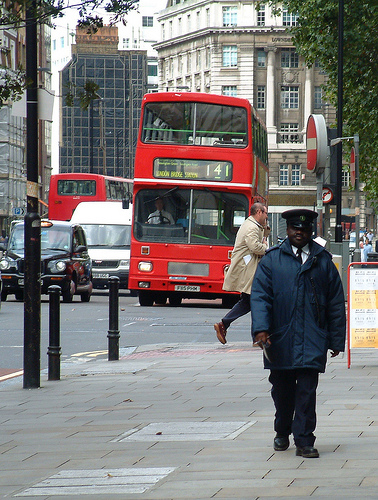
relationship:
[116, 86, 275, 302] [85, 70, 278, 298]
windshield on bus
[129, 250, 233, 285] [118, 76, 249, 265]
headlight on bus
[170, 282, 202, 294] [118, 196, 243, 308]
plate on bus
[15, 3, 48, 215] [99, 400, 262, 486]
pole on sidewalk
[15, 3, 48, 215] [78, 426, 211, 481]
pole on sidewalk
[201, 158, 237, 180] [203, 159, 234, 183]
number on bus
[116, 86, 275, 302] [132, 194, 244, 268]
windshield on bottom deck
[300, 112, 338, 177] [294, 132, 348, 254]
sign on pole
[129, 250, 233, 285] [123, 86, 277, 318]
headlight on bus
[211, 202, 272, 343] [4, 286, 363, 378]
man crossing street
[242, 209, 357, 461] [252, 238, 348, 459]
man in uniform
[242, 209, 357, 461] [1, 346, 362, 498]
man walking down sidewalk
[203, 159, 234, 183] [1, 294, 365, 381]
bus driving down road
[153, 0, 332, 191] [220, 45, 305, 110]
building with window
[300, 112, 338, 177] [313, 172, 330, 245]
sign attached to pole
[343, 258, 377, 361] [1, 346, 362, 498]
advertisement sitting on sidewalk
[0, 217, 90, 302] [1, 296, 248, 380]
car driving on road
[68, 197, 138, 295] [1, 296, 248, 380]
car driving on road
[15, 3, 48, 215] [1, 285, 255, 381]
pole next to street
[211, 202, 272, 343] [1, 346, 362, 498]
man walking on sidewalk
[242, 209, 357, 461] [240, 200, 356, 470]
man in outfit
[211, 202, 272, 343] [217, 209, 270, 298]
man in coat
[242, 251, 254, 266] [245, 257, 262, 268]
paper sticking out of pocket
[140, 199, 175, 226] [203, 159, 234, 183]
driver of bus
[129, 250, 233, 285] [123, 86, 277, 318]
headlight of bus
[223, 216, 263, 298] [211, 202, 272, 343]
coat worn by man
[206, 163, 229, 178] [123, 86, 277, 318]
number on bus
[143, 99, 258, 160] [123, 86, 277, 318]
window of bus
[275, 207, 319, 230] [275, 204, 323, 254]
hat on head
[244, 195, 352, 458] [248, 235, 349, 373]
policeman wearing coat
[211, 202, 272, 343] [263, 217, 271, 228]
man talking on phone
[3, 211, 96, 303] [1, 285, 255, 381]
bentley driving on street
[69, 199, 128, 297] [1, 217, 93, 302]
van driving behind bentley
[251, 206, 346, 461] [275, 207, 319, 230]
man wearing hat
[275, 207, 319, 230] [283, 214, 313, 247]
hat covering head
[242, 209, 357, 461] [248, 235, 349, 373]
man wearing coat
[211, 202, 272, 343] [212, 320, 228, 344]
man wearing shoe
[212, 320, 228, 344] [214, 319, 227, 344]
shoe covering foot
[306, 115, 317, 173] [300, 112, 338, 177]
edge lining sign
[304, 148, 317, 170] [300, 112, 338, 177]
edge lining sign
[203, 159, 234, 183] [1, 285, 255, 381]
bus driving on street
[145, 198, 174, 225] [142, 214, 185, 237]
man sitting in driver's seat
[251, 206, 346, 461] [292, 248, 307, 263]
man wearing tie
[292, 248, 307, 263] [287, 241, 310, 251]
tie wrapped around neck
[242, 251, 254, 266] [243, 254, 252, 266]
paper stuck inside paper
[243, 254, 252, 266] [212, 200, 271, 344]
paper sewn on jacket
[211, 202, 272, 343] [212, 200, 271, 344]
man wearing jacket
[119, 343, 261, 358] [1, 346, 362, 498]
tile covering sidewalk